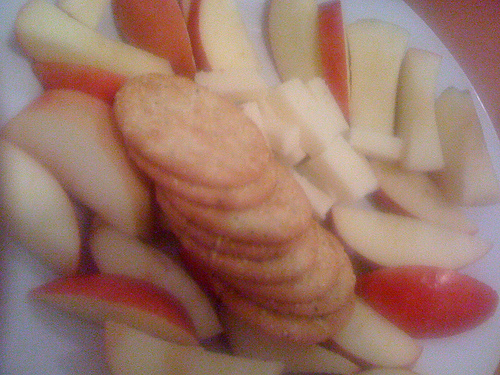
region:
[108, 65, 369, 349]
row of crackers on top of apples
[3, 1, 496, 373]
apple slices on top of plate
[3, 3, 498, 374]
apple slices with red skins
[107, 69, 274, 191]
top most cracker on a row of crackers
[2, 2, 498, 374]
white ceramic dinner plate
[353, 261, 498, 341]
apple slice with red peel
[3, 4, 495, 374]
several pieces of sliced apple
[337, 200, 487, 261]
inside flesh of sliced apple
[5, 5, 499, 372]
fruit and crackers are on a plate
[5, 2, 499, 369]
the ceramic plate is white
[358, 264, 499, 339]
the apple slice has red skin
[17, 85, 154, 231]
the skin of the apple is light yellow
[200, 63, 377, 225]
cubes of cheese are on the plate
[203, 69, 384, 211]
white cheese is on the plate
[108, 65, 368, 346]
the crackers are round and salted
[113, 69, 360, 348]
the crackers are lined up in a row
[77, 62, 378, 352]
the crackers are lying on the apples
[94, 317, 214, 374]
an apple is turning brown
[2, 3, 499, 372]
Plate with apples, cheese and crackers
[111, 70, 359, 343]
A group of oval crackers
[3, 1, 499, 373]
Red apple cut in slices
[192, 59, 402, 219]
White cheese cut in rectangular cubes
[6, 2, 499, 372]
Round white plate with food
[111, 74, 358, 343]
Row of eight crackers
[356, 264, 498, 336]
Slice of apple with red peel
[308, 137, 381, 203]
Pale white cheese cube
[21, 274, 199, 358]
Apple slice and its shadow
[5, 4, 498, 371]
Plate of cheese, crackers and apple slices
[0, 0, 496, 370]
White plate of food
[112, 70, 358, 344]
Row of seasoned crackers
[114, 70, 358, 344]
Brown crackers on apples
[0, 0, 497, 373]
Plate of apples, cheese and crackers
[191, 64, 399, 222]
Chunks of white cheese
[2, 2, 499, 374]
Slices of red apple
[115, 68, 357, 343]
Crackers with seasoning and salt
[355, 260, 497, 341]
Red peel of an apple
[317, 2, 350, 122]
Thin slice of apple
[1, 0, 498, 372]
Snacks on a white plate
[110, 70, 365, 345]
small row of ritz crackers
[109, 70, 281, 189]
crispy brown Ritz cracker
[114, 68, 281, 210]
two cripsy Ritz crackers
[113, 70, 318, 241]
three crispy round crackers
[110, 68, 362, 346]
crispy crackers on top of each other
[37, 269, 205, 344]
sliced of a red apple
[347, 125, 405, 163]
small cut piece of white cheese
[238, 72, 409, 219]
rectangular diced white cheese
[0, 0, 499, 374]
apple slices crackers and cheese on a plate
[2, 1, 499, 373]
plate of cracker fruit and cheese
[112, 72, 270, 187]
cracker is on the plate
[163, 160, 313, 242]
cracker is on the plate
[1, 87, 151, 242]
apple is on the table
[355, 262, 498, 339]
apple is on the plate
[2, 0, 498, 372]
plate is white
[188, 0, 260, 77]
apple is on the plate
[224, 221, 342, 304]
cracker is on the plate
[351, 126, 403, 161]
cheese square is on the plate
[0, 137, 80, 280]
apple is on the plate